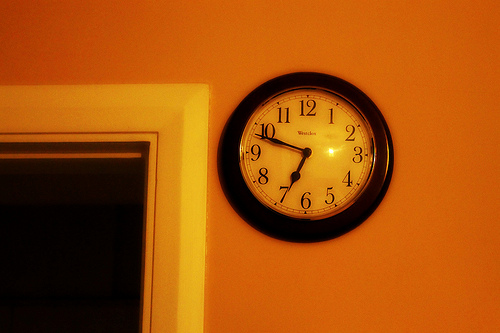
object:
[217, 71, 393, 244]
clock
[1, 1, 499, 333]
wall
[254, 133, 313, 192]
hands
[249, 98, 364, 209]
numbers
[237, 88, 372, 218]
frame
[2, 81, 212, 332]
door trim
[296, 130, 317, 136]
name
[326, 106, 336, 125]
number 1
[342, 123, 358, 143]
number 2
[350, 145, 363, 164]
number 3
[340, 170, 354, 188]
number 4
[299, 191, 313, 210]
number 6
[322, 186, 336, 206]
number 5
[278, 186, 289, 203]
number 7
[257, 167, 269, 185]
number 8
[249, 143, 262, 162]
number 9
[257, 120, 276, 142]
number 10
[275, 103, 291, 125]
number 11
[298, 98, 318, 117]
number 12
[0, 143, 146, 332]
doorway